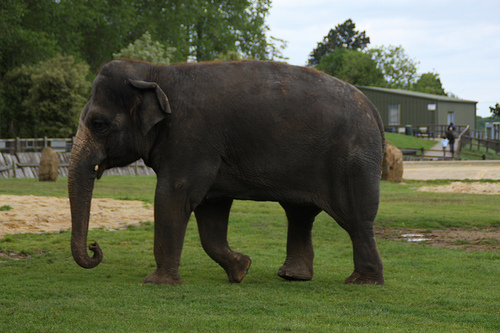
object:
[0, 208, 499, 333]
trimmed grass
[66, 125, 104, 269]
trunk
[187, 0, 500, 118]
sky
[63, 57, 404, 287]
elephant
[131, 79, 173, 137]
ear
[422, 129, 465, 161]
ramp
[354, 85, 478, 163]
building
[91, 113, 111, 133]
eye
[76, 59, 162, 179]
head